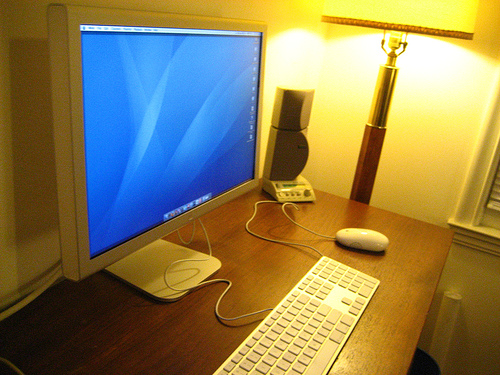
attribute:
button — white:
[329, 328, 346, 345]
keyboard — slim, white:
[209, 253, 383, 374]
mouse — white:
[334, 226, 393, 257]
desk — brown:
[2, 178, 460, 374]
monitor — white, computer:
[44, 3, 273, 285]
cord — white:
[244, 195, 325, 259]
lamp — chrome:
[317, 1, 481, 208]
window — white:
[444, 77, 499, 264]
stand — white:
[104, 236, 224, 301]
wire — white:
[0, 267, 64, 323]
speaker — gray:
[259, 82, 320, 206]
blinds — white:
[484, 162, 499, 220]